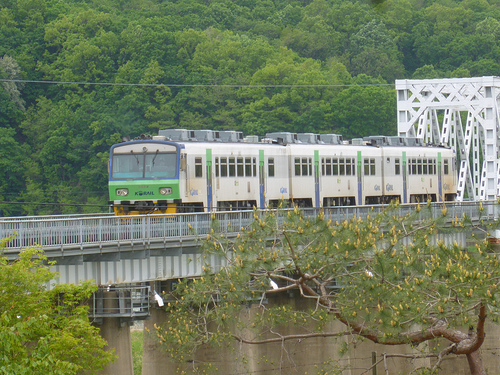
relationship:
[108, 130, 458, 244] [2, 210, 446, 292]
train crosses bridge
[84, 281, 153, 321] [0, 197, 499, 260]
deck under bridge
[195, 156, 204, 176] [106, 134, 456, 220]
window on train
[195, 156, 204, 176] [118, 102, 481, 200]
window on train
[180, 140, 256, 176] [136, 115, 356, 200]
window on train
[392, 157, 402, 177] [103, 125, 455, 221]
window on train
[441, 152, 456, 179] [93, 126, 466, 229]
window on train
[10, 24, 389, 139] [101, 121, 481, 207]
trees behind train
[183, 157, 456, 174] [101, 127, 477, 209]
windows on train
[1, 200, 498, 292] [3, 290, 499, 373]
tracks above water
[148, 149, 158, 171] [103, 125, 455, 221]
windsheild wiper on train